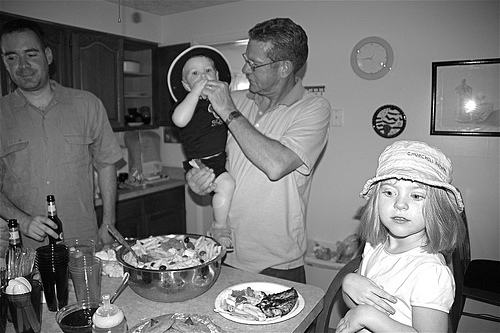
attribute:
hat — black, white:
[166, 46, 234, 102]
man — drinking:
[0, 26, 123, 259]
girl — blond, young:
[338, 180, 467, 332]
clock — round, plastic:
[350, 35, 394, 79]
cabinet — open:
[71, 28, 191, 127]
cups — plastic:
[32, 236, 108, 309]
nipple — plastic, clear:
[93, 294, 115, 316]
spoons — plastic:
[4, 278, 39, 332]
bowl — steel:
[114, 233, 226, 303]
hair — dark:
[1, 19, 43, 44]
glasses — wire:
[242, 53, 290, 75]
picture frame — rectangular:
[428, 60, 499, 138]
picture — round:
[370, 103, 407, 139]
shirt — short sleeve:
[230, 90, 332, 244]